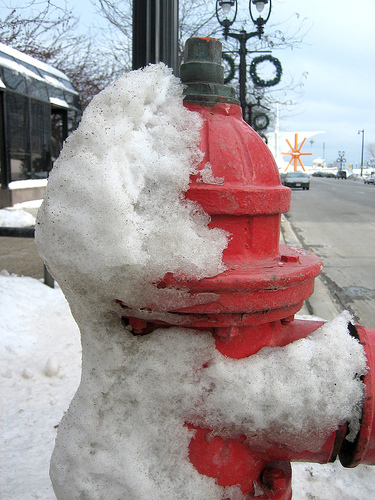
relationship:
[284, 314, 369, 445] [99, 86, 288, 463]
pipe on hydrant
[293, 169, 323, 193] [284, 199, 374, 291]
car on street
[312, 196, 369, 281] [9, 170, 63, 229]
road by sidewalks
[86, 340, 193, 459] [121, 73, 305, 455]
snow on hydrant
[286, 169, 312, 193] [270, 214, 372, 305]
car on street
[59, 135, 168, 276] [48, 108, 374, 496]
snow on hydrant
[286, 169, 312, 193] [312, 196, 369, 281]
car on road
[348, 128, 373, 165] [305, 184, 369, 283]
lamp post on street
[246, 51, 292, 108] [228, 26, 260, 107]
wreath on post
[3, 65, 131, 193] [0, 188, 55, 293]
building on sidewalk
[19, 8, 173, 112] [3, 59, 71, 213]
trees behind building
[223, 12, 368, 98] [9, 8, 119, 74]
sky above trees